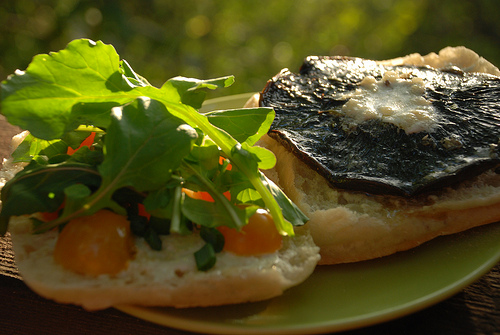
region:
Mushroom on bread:
[257, 50, 497, 199]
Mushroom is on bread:
[257, 47, 499, 196]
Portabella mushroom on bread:
[255, 50, 498, 199]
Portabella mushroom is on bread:
[242, 43, 498, 200]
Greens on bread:
[1, 35, 311, 247]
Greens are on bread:
[0, 35, 311, 272]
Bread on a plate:
[3, 36, 496, 318]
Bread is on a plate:
[2, 32, 497, 313]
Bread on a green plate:
[1, 34, 498, 314]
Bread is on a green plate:
[2, 32, 498, 315]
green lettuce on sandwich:
[77, 69, 264, 247]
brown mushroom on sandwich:
[293, 57, 465, 177]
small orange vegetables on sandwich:
[18, 177, 350, 253]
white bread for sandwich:
[265, 45, 495, 273]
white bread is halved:
[13, 51, 479, 299]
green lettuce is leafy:
[35, 38, 324, 263]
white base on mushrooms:
[332, 96, 428, 146]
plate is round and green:
[19, 100, 471, 314]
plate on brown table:
[0, 270, 487, 333]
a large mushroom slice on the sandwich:
[256, 51, 497, 195]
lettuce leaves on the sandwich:
[8, 38, 308, 235]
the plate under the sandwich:
[98, 216, 497, 327]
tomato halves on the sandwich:
[43, 192, 283, 274]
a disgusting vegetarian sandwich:
[4, 37, 498, 309]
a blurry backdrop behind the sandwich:
[6, 5, 497, 94]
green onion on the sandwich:
[185, 240, 220, 274]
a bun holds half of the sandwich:
[5, 211, 318, 311]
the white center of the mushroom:
[330, 70, 440, 136]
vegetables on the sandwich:
[13, 35, 309, 265]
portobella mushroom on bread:
[247, 44, 498, 206]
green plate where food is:
[326, 275, 483, 324]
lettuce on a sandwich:
[3, 39, 221, 180]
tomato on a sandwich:
[55, 207, 142, 274]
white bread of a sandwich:
[313, 211, 444, 259]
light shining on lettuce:
[69, 46, 101, 94]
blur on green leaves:
[175, 0, 355, 60]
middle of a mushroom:
[353, 71, 433, 141]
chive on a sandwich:
[191, 239, 218, 275]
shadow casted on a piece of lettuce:
[26, 163, 121, 209]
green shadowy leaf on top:
[59, 56, 169, 131]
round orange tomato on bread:
[67, 221, 107, 263]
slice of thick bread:
[165, 265, 202, 305]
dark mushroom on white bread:
[338, 118, 353, 142]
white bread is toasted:
[336, 213, 366, 245]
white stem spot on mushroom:
[342, 72, 418, 138]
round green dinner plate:
[402, 288, 420, 305]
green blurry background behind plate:
[228, 25, 262, 50]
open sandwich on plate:
[298, 205, 328, 262]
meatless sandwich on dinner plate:
[259, 237, 403, 273]